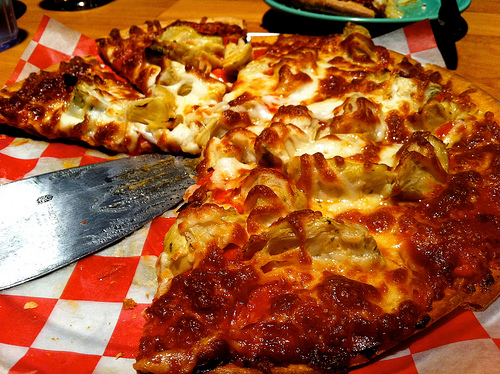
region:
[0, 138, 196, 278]
The utensil is silver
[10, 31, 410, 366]
The paper is checkered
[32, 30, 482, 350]
The pizza is cut into slices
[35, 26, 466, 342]
The pizza has cheese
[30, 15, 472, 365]
The pizza is on top of a paper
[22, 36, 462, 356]
The paper is red and white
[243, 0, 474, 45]
The plate is green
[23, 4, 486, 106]
The table is wood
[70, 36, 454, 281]
Green peppers on the pizza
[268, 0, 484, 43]
Food in the bowl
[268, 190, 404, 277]
cooked chicken on a pizza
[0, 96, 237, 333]
silver serving utensil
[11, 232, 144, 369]
red and white paper underneath the pizza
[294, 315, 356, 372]
burnt cheese on the crust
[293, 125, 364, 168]
melted cheese on the pizza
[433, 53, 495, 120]
brown crust on a pizza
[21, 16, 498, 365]
a cooked pizza on a piece of paper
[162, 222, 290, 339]
browned cheese on top of the pizza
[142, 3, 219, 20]
wood table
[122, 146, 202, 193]
pizza grease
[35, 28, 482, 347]
cheese and mushroom pizza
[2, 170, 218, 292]
serving spatula for pizza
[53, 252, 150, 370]
red and white checkered table cloth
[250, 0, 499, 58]
green plate behind pizza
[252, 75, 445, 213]
cheese and mushrooms on the pizza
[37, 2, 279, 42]
brown wooden table with pizza on it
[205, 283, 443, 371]
crispy edge of pizza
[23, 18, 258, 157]
two slices of pizza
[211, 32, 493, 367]
half of a cheese and mushroom pizza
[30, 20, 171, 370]
pizza and a serving spatula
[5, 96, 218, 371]
pizza missing slices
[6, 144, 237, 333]
used to lift the pizza on to plate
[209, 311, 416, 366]
cheese burned on the crust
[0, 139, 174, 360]
pizza on red and white paper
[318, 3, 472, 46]
green bowl next to the pizza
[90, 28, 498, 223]
pizza is on a table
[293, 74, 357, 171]
cheese on the pizza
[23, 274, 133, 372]
paper pizza is on is checkered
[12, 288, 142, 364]
crumbs on the paper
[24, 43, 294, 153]
pizza cut into slices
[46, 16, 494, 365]
bright red and yellow pizza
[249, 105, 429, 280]
chicken on a pizza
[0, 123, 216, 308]
silver spatula under a pizza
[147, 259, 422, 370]
half burnt red sauce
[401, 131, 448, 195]
chicken with burnt cheese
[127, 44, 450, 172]
white melted cheese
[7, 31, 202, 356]
white and red checkered paper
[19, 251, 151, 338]
pizza crumbs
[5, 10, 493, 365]
pizza sitting on a table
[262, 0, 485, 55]
aqua colored plate with food on it